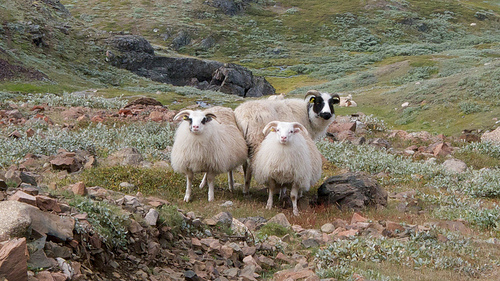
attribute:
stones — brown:
[31, 141, 413, 264]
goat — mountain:
[166, 102, 254, 206]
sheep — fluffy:
[102, 21, 417, 250]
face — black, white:
[303, 84, 393, 144]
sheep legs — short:
[263, 177, 303, 215]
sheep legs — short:
[177, 167, 237, 201]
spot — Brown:
[290, 194, 297, 202]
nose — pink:
[187, 113, 200, 139]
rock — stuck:
[0, 235, 29, 279]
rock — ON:
[112, 36, 273, 98]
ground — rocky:
[28, 135, 98, 172]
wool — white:
[176, 135, 245, 172]